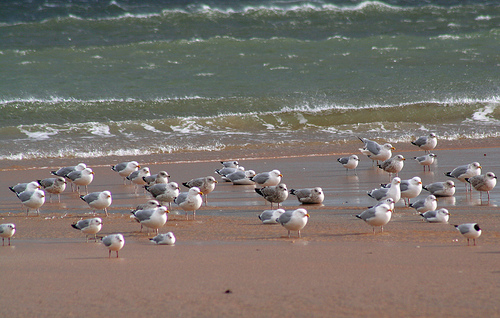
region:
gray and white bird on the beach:
[97, 232, 129, 268]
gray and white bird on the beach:
[275, 204, 322, 241]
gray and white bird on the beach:
[356, 197, 390, 233]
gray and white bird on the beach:
[413, 195, 446, 225]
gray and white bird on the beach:
[175, 182, 207, 231]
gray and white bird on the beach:
[26, 194, 51, 217]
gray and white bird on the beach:
[85, 187, 115, 207]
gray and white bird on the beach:
[115, 157, 139, 182]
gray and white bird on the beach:
[336, 148, 363, 177]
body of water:
[118, 55, 250, 101]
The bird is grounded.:
[1, 216, 31, 258]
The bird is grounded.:
[62, 210, 104, 247]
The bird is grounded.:
[97, 225, 139, 269]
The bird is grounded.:
[72, 184, 122, 220]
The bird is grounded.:
[124, 200, 169, 237]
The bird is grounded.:
[173, 185, 217, 245]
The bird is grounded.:
[275, 203, 318, 268]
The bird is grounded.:
[349, 196, 399, 253]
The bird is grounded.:
[451, 214, 491, 261]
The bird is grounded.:
[330, 145, 370, 188]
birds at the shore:
[19, 123, 468, 246]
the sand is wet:
[200, 192, 309, 275]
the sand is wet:
[291, 188, 386, 268]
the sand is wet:
[317, 132, 397, 242]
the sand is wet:
[144, 195, 277, 271]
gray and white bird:
[181, 175, 218, 204]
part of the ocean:
[1, 0, 499, 160]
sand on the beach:
[0, 138, 499, 313]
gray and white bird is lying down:
[288, 185, 325, 205]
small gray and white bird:
[148, 229, 176, 245]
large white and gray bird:
[411, 127, 436, 153]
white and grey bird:
[64, 166, 94, 191]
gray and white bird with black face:
[454, 219, 481, 245]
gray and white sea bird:
[356, 132, 396, 164]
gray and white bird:
[465, 168, 496, 200]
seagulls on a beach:
[37, 152, 446, 261]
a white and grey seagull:
[247, 163, 287, 190]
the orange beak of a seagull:
[302, 210, 312, 219]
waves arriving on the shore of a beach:
[15, 64, 411, 166]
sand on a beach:
[201, 250, 318, 290]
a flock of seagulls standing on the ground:
[0, 143, 497, 268]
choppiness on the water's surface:
[166, 53, 322, 85]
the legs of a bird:
[103, 243, 122, 258]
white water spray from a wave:
[16, 88, 95, 113]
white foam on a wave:
[30, 125, 162, 142]